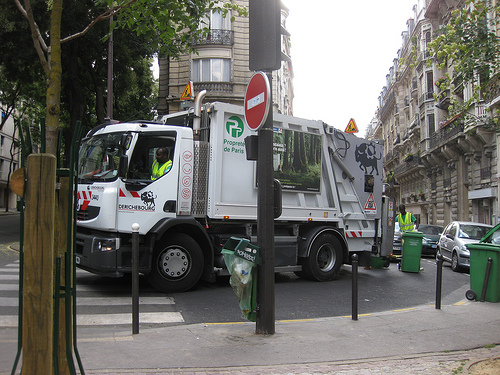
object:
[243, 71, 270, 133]
sign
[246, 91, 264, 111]
dash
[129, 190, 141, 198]
stripe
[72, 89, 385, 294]
truck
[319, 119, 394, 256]
receptacle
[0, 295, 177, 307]
stripes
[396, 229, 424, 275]
garbage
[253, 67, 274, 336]
post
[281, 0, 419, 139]
sky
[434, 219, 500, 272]
car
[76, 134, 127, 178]
windshield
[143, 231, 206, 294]
wheel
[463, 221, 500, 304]
garbage can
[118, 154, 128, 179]
mirror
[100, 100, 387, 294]
side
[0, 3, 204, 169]
tree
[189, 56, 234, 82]
windows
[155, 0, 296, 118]
building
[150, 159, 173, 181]
vest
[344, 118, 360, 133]
sign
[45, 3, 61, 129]
moss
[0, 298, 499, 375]
sidewalk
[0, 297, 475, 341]
curb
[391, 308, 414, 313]
yellow lines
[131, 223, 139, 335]
pole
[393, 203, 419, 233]
garbageman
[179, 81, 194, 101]
sign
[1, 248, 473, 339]
street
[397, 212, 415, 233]
yellow vest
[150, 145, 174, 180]
man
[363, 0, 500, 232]
building